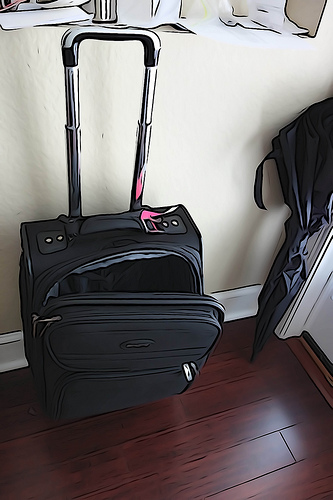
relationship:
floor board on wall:
[205, 291, 264, 332] [131, 46, 283, 331]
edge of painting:
[0, 15, 321, 37] [5, 1, 327, 36]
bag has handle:
[17, 204, 228, 432] [55, 19, 159, 208]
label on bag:
[141, 204, 179, 222] [16, 200, 228, 418]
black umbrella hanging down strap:
[249, 97, 332, 366] [244, 152, 277, 218]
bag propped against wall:
[17, 204, 228, 432] [189, 73, 232, 185]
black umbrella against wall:
[249, 97, 332, 366] [2, 2, 328, 376]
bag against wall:
[17, 204, 228, 432] [2, 2, 328, 376]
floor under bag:
[5, 321, 316, 496] [17, 204, 228, 432]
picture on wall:
[2, 2, 327, 35] [164, 38, 320, 97]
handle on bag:
[60, 18, 161, 220] [17, 204, 228, 432]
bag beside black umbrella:
[17, 204, 228, 432] [249, 97, 332, 366]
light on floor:
[204, 394, 321, 498] [5, 321, 316, 496]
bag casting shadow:
[17, 204, 228, 432] [42, 418, 206, 493]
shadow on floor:
[42, 418, 206, 493] [5, 321, 316, 496]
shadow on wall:
[216, 85, 332, 290] [0, 0, 333, 334]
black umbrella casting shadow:
[249, 97, 332, 366] [216, 85, 332, 290]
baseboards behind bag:
[1, 270, 273, 377] [17, 204, 228, 432]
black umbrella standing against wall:
[251, 87, 331, 369] [20, 0, 278, 344]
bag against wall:
[17, 204, 228, 432] [0, 0, 333, 334]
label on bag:
[140, 204, 180, 221] [17, 204, 228, 432]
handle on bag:
[55, 19, 159, 208] [17, 204, 228, 432]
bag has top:
[17, 204, 228, 432] [19, 205, 221, 321]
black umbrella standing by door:
[249, 97, 332, 366] [283, 234, 330, 390]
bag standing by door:
[17, 204, 228, 432] [283, 234, 330, 390]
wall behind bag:
[0, 0, 333, 334] [17, 204, 228, 432]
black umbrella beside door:
[249, 97, 332, 366] [281, 231, 332, 391]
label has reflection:
[140, 204, 180, 221] [134, 164, 146, 201]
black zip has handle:
[71, 350, 198, 381] [60, 18, 161, 220]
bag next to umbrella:
[16, 200, 228, 418] [238, 92, 327, 364]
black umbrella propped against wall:
[249, 97, 332, 366] [171, 50, 229, 204]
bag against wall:
[17, 204, 228, 432] [84, 82, 319, 233]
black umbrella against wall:
[249, 97, 332, 366] [84, 82, 319, 233]